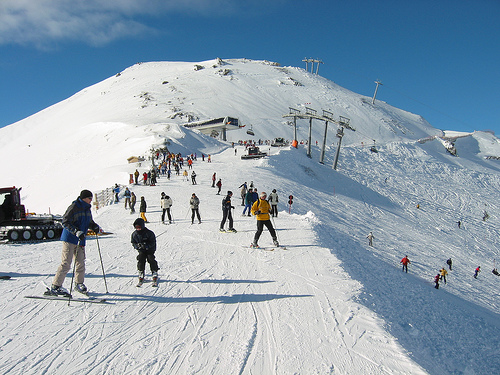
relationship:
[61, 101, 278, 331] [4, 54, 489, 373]
snow on mountain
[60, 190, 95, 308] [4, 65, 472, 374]
skier on ski slope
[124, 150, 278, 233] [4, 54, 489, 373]
skiers on mountain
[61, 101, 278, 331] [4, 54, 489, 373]
snow atop mountain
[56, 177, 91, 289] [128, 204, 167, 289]
man teaching kid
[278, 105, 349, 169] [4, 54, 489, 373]
poles on mountain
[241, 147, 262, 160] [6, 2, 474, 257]
snow machine in background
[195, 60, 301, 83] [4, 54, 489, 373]
rocks on mountain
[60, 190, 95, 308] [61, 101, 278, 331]
skier in snow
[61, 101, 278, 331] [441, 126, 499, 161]
snow on hill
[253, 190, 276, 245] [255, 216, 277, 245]
person wearing pants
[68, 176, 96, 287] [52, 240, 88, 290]
person wearing pants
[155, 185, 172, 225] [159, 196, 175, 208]
person wearing jacket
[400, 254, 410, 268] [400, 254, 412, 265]
person wearing jacket